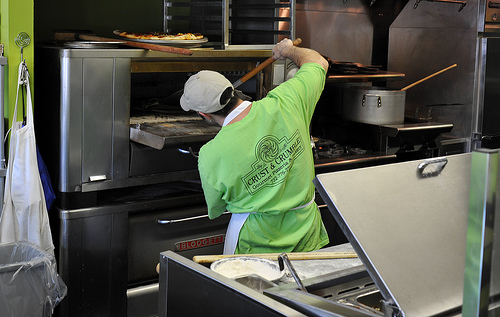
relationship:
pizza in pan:
[121, 30, 203, 41] [113, 30, 209, 48]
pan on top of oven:
[113, 30, 209, 48] [36, 40, 301, 316]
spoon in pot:
[399, 63, 458, 92] [344, 86, 404, 125]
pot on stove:
[344, 86, 404, 125] [309, 118, 469, 251]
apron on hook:
[0, 61, 58, 270] [16, 31, 31, 73]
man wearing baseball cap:
[179, 38, 332, 256] [179, 69, 235, 113]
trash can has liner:
[0, 240, 53, 316] [0, 239, 68, 315]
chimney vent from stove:
[362, 1, 410, 86] [309, 118, 469, 251]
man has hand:
[179, 38, 332, 256] [271, 37, 292, 58]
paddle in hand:
[233, 37, 304, 102] [271, 37, 292, 58]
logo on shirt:
[241, 129, 307, 195] [198, 63, 330, 256]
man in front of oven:
[179, 38, 332, 256] [36, 40, 301, 316]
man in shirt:
[179, 38, 332, 256] [198, 63, 330, 256]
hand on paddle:
[271, 37, 292, 58] [233, 37, 304, 102]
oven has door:
[36, 40, 301, 316] [130, 122, 225, 152]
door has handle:
[130, 122, 225, 152] [188, 145, 199, 158]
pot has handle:
[344, 86, 404, 125] [363, 93, 381, 108]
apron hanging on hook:
[0, 61, 58, 270] [16, 31, 31, 73]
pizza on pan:
[121, 30, 203, 41] [113, 30, 209, 48]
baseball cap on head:
[179, 69, 235, 113] [183, 69, 235, 125]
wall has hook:
[1, 1, 35, 168] [16, 31, 31, 73]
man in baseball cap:
[179, 38, 332, 256] [179, 69, 235, 113]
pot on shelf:
[344, 86, 404, 125] [317, 115, 454, 155]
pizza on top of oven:
[121, 30, 203, 41] [36, 40, 301, 316]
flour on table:
[211, 256, 287, 284] [211, 240, 363, 294]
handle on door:
[188, 145, 199, 158] [130, 122, 225, 152]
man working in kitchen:
[179, 38, 332, 256] [1, 1, 500, 316]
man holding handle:
[179, 38, 332, 256] [188, 145, 199, 158]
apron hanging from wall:
[0, 61, 58, 270] [1, 1, 35, 168]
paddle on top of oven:
[50, 28, 194, 56] [36, 40, 301, 316]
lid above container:
[311, 151, 500, 315] [347, 288, 387, 316]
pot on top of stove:
[344, 86, 404, 125] [309, 118, 469, 251]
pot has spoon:
[344, 86, 404, 125] [399, 63, 458, 92]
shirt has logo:
[198, 63, 330, 256] [241, 129, 307, 195]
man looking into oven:
[179, 38, 332, 256] [36, 40, 301, 316]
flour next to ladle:
[211, 256, 287, 284] [278, 254, 309, 295]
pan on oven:
[113, 30, 209, 48] [36, 40, 301, 316]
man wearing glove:
[179, 38, 332, 256] [271, 37, 294, 58]